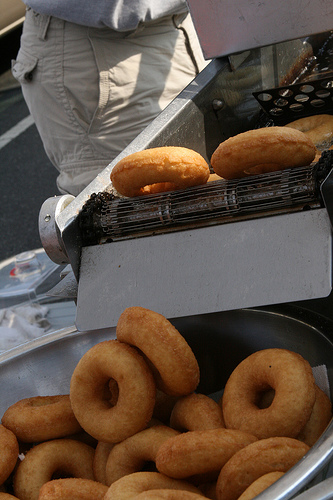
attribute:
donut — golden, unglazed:
[108, 143, 214, 199]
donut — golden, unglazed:
[206, 122, 318, 184]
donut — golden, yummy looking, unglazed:
[112, 303, 203, 401]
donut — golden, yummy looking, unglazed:
[220, 344, 320, 444]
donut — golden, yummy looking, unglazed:
[66, 335, 161, 447]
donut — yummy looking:
[152, 425, 261, 482]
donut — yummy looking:
[210, 434, 315, 500]